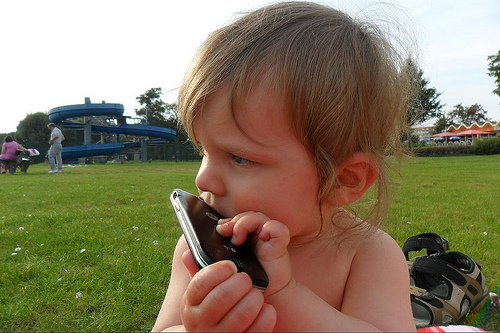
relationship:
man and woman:
[22, 115, 83, 180] [4, 117, 47, 188]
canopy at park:
[441, 106, 491, 144] [6, 151, 186, 281]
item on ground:
[395, 223, 472, 316] [385, 190, 487, 227]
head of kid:
[148, 38, 345, 242] [125, 33, 422, 294]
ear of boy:
[317, 125, 422, 209] [148, 0, 422, 333]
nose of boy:
[170, 144, 230, 194] [148, 0, 422, 333]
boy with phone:
[148, 0, 422, 333] [153, 215, 319, 277]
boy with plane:
[148, 0, 422, 333] [182, 214, 259, 272]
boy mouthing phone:
[148, 0, 422, 333] [169, 174, 277, 292]